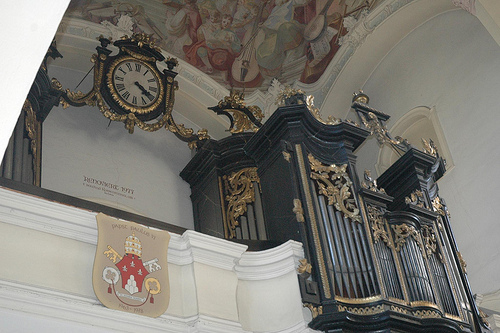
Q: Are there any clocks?
A: Yes, there is a clock.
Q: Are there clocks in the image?
A: Yes, there is a clock.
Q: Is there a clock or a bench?
A: Yes, there is a clock.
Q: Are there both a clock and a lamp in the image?
A: No, there is a clock but no lamps.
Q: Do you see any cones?
A: No, there are no cones.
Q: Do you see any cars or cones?
A: No, there are no cones or cars.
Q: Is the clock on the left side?
A: Yes, the clock is on the left of the image.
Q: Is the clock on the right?
A: No, the clock is on the left of the image.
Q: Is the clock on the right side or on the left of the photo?
A: The clock is on the left of the image.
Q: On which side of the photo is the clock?
A: The clock is on the left of the image.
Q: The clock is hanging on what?
A: The clock is hanging on the wall.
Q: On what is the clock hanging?
A: The clock is hanging on the wall.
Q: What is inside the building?
A: The clock is inside the building.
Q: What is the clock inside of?
A: The clock is inside the building.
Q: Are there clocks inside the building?
A: Yes, there is a clock inside the building.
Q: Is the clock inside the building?
A: Yes, the clock is inside the building.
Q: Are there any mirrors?
A: No, there are no mirrors.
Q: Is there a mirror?
A: No, there are no mirrors.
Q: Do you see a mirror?
A: No, there are no mirrors.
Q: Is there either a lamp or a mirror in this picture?
A: No, there are no mirrors or lamps.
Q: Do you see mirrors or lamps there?
A: No, there are no mirrors or lamps.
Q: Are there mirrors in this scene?
A: No, there are no mirrors.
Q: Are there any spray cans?
A: No, there are no spray cans.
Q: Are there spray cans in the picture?
A: No, there are no spray cans.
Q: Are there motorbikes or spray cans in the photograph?
A: No, there are no spray cans or motorbikes.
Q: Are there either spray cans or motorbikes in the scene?
A: No, there are no spray cans or motorbikes.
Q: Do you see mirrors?
A: No, there are no mirrors.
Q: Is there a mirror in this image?
A: No, there are no mirrors.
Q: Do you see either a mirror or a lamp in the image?
A: No, there are no mirrors or lamps.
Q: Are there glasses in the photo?
A: No, there are no glasses.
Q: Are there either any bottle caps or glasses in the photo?
A: No, there are no glasses or bottle caps.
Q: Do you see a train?
A: No, there are no trains.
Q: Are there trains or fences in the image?
A: No, there are no trains or fences.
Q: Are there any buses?
A: No, there are no buses.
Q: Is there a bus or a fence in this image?
A: No, there are no buses or fences.